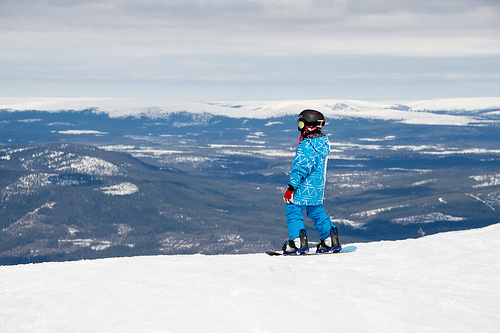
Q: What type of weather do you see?
A: It is overcast.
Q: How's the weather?
A: It is overcast.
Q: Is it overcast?
A: Yes, it is overcast.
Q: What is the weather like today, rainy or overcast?
A: It is overcast.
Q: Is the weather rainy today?
A: No, it is overcast.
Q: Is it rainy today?
A: No, it is overcast.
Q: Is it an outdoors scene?
A: Yes, it is outdoors.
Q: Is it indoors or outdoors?
A: It is outdoors.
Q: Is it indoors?
A: No, it is outdoors.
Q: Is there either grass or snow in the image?
A: Yes, there is snow.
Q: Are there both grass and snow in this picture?
A: No, there is snow but no grass.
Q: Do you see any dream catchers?
A: No, there are no dream catchers.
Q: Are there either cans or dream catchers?
A: No, there are no dream catchers or cans.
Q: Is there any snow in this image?
A: Yes, there is snow.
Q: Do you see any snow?
A: Yes, there is snow.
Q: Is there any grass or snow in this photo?
A: Yes, there is snow.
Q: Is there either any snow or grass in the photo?
A: Yes, there is snow.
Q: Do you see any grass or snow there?
A: Yes, there is snow.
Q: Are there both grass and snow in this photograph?
A: No, there is snow but no grass.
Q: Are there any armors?
A: No, there are no armors.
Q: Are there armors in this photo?
A: No, there are no armors.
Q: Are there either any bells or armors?
A: No, there are no armors or bells.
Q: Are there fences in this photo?
A: No, there are no fences.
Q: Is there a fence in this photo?
A: No, there are no fences.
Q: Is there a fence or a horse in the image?
A: No, there are no fences or horses.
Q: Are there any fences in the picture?
A: No, there are no fences.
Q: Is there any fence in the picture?
A: No, there are no fences.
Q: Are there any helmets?
A: Yes, there is a helmet.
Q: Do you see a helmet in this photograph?
A: Yes, there is a helmet.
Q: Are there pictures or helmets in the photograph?
A: Yes, there is a helmet.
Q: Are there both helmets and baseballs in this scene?
A: No, there is a helmet but no baseballs.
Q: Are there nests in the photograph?
A: No, there are no nests.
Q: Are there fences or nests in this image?
A: No, there are no nests or fences.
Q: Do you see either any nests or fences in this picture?
A: No, there are no nests or fences.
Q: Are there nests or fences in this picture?
A: No, there are no nests or fences.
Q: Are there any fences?
A: No, there are no fences.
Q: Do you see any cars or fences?
A: No, there are no fences or cars.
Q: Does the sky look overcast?
A: Yes, the sky is overcast.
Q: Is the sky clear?
A: No, the sky is overcast.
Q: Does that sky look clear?
A: No, the sky is overcast.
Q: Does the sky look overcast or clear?
A: The sky is overcast.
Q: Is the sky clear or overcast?
A: The sky is overcast.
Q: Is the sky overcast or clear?
A: The sky is overcast.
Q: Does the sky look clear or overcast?
A: The sky is overcast.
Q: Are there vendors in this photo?
A: No, there are no vendors.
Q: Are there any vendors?
A: No, there are no vendors.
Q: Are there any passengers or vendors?
A: No, there are no vendors or passengers.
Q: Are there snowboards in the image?
A: Yes, there is a snowboard.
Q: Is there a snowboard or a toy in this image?
A: Yes, there is a snowboard.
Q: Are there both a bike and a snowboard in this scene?
A: No, there is a snowboard but no bikes.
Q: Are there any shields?
A: No, there are no shields.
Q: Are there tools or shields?
A: No, there are no shields or tools.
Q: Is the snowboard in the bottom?
A: Yes, the snowboard is in the bottom of the image.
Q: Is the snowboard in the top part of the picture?
A: No, the snowboard is in the bottom of the image.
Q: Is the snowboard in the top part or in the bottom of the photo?
A: The snowboard is in the bottom of the image.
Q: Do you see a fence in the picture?
A: No, there are no fences.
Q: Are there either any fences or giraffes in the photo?
A: No, there are no fences or giraffes.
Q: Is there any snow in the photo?
A: Yes, there is snow.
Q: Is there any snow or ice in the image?
A: Yes, there is snow.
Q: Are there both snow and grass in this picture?
A: No, there is snow but no grass.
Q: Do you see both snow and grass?
A: No, there is snow but no grass.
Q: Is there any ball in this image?
A: No, there are no balls.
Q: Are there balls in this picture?
A: No, there are no balls.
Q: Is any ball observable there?
A: No, there are no balls.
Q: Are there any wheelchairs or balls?
A: No, there are no balls or wheelchairs.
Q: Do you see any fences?
A: No, there are no fences.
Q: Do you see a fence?
A: No, there are no fences.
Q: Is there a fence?
A: No, there are no fences.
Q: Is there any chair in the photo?
A: No, there are no chairs.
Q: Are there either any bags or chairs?
A: No, there are no chairs or bags.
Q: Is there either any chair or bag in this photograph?
A: No, there are no chairs or bags.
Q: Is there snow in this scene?
A: Yes, there is snow.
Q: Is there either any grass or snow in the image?
A: Yes, there is snow.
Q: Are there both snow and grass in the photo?
A: No, there is snow but no grass.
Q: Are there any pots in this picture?
A: No, there are no pots.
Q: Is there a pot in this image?
A: No, there are no pots.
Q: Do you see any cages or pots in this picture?
A: No, there are no pots or cages.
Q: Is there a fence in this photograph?
A: No, there are no fences.